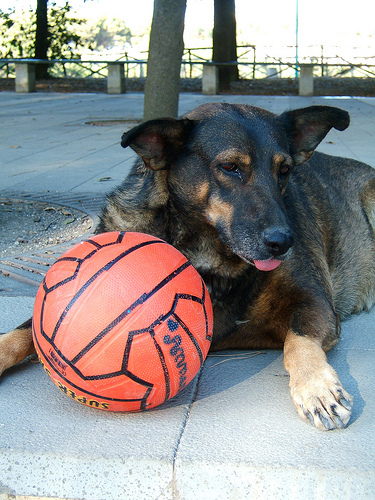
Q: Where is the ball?
A: On the ground.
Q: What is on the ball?
A: Black lines.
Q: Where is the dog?
A: Laying on the ground.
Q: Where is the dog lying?
A: On the ground.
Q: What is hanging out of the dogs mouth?
A: Tongue.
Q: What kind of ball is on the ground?
A: A basketball.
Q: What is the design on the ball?
A: Black lines.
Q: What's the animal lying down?
A: Dog.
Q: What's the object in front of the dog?
A: Basketball.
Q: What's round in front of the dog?
A: Ball.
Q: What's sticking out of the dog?
A: Tongue.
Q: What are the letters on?
A: Ball.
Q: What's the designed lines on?
A: Basketball.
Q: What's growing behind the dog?
A: Tree.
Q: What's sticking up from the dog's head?
A: Ears.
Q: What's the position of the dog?
A: Lying down.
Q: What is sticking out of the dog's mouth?
A: A tongue.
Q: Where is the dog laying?
A: On the ground.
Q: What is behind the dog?
A: A bench.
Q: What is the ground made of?
A: Cement.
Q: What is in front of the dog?
A: A ball.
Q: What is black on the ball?
A: The lines.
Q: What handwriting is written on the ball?
A: Cursive.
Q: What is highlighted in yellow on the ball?
A: The letters.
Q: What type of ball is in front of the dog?
A: Soccer.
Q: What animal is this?
A: Dog.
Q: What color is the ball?
A: Orange.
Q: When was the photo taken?
A: Daytime.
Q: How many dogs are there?
A: One.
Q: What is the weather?
A: Sunny.